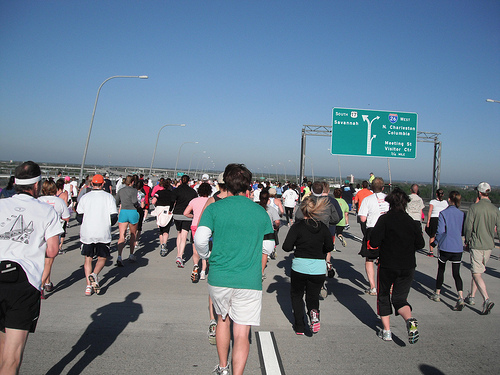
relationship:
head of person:
[221, 162, 254, 197] [188, 161, 278, 373]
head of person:
[382, 187, 412, 211] [367, 189, 424, 343]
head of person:
[54, 177, 67, 189] [52, 173, 70, 204]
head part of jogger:
[89, 172, 106, 189] [74, 172, 117, 297]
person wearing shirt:
[188, 161, 278, 373] [194, 195, 273, 291]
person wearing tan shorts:
[72, 174, 120, 296] [202, 281, 265, 331]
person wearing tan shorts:
[0, 157, 68, 373] [202, 281, 265, 331]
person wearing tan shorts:
[115, 174, 147, 264] [202, 281, 265, 331]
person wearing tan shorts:
[357, 173, 387, 293] [202, 281, 265, 331]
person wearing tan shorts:
[188, 161, 278, 373] [202, 281, 265, 331]